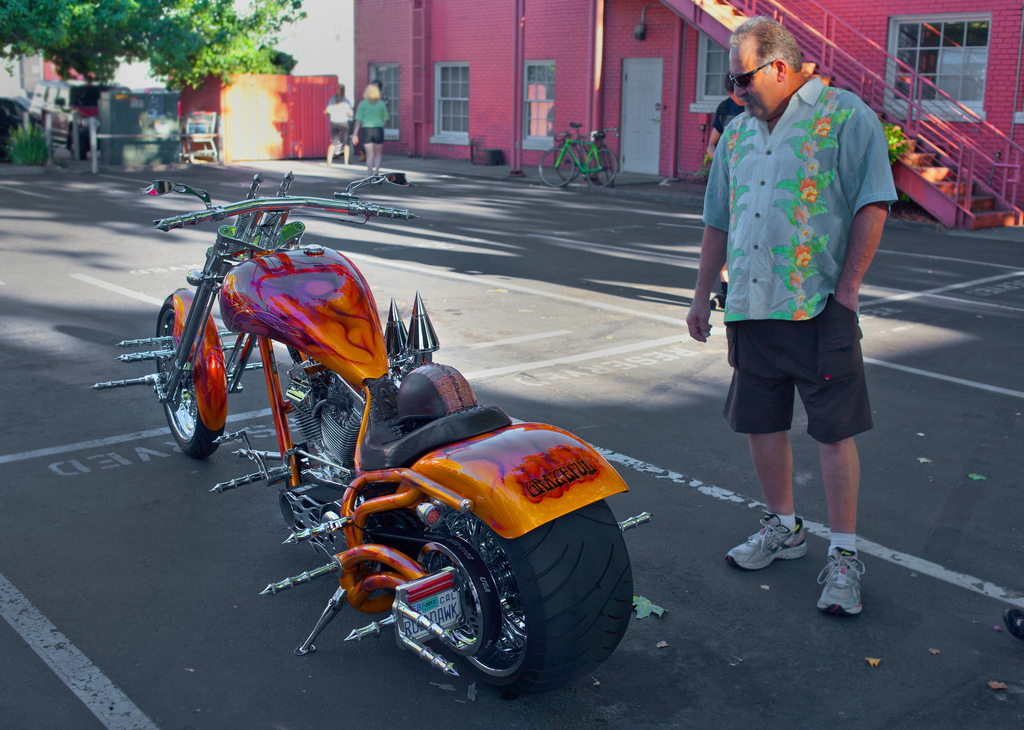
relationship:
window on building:
[430, 58, 470, 138] [344, 0, 1015, 245]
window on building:
[366, 60, 408, 136] [344, 0, 1015, 245]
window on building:
[885, 14, 997, 109] [344, 0, 1015, 245]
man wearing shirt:
[685, 10, 895, 622] [685, 80, 905, 322]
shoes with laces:
[727, 515, 887, 623] [755, 515, 782, 547]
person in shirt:
[347, 77, 396, 182] [350, 96, 393, 131]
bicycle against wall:
[536, 120, 622, 188] [351, 3, 1018, 232]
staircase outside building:
[660, 4, 1016, 221] [350, 4, 1017, 205]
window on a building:
[433, 60, 468, 137] [344, 0, 1015, 245]